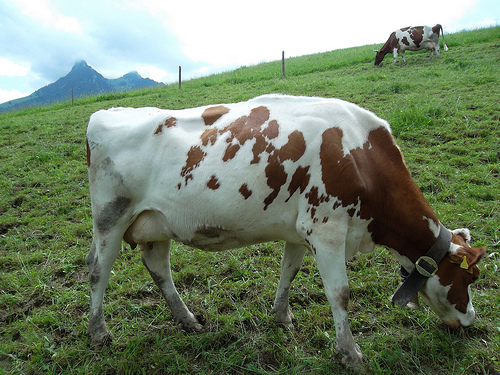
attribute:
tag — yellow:
[460, 255, 470, 271]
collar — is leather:
[396, 219, 453, 317]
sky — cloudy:
[203, 2, 355, 35]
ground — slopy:
[6, 25, 496, 372]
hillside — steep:
[0, 20, 498, 371]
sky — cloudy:
[4, 7, 347, 50]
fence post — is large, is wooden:
[169, 64, 193, 95]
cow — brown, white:
[372, 17, 455, 69]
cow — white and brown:
[63, 92, 468, 349]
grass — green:
[358, 50, 440, 117]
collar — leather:
[390, 215, 452, 321]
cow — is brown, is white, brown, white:
[77, 90, 493, 372]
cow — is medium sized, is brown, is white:
[367, 18, 452, 68]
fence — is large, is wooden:
[62, 82, 79, 105]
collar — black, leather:
[413, 235, 440, 287]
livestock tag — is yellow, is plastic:
[456, 254, 471, 270]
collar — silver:
[379, 219, 451, 309]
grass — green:
[3, 24, 475, 370]